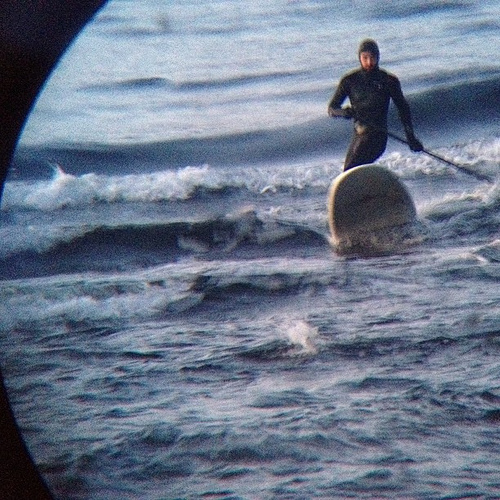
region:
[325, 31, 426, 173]
Man wearing a black wet suit.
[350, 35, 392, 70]
Black suit covers man's whole head.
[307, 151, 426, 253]
Man surfing waves on a white board.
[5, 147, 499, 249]
Long white waves cover the water.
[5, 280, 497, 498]
Several ripples spread out in the water.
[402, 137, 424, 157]
Man is wearing black gloves on his hands.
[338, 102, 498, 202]
Man uses long black paddle in the water.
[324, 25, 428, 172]
Skinny man surfing in the water.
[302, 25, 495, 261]
Man standing tall on his white surf board.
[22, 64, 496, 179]
Medium wave runs all behind man on the white board.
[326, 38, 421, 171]
Man wearing all black wetsuit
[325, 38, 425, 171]
Man holding black paddle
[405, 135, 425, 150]
Hand holding black paddle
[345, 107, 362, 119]
Hand holding black paddle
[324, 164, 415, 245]
White surfboard in water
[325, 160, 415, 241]
White surfboard is wet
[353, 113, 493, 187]
Black paddle in water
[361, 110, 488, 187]
Black paddle is wet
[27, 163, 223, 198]
Small wave in water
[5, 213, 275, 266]
Small wave next to man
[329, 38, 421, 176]
man in a wet suit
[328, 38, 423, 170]
guy in a wet suit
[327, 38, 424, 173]
person in a wet suit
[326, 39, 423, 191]
man holding an oar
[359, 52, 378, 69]
face of a man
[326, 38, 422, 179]
person holding an oar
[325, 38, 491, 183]
guy holding an oar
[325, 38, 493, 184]
male holding an oar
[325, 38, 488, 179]
human holding an oar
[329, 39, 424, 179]
homo sapien in a wet suit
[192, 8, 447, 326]
a person surfing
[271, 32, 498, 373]
a person paddle boarding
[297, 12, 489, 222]
a person paddle boarding in the water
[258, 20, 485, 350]
a person on a paddle board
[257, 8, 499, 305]
a person holding a paddle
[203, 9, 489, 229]
a person in a body of water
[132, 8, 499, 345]
a person paddle boarding in the water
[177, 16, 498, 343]
a paddle boarder in the water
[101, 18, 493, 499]
a body of water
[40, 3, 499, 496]
a body of water with waves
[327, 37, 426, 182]
man dressed in black wetsuit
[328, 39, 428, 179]
man dressed in black wetsuit with wetcap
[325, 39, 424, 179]
man paddling an oar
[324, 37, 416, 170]
man standing on a surfboar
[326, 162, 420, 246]
white surfboard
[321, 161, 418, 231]
white surfboard the man in the black wetsuit is standing on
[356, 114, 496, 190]
oar being used to paddle to shore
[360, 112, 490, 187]
oar being used by man in black wetsuit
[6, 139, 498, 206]
wave in the ocean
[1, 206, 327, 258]
ocean wave